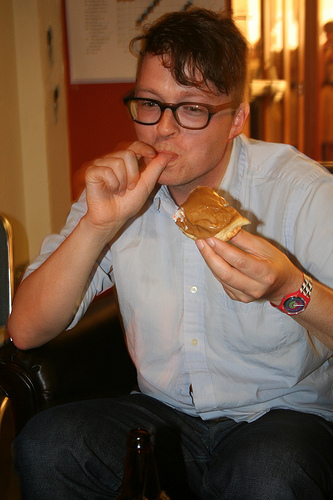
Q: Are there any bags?
A: No, there are no bags.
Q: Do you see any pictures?
A: No, there are no pictures.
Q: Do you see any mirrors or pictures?
A: No, there are no pictures or mirrors.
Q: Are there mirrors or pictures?
A: No, there are no pictures or mirrors.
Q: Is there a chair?
A: Yes, there is a chair.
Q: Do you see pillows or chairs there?
A: Yes, there is a chair.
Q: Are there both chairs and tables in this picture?
A: No, there is a chair but no tables.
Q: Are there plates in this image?
A: No, there are no plates.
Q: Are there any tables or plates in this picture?
A: No, there are no plates or tables.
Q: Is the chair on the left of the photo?
A: Yes, the chair is on the left of the image.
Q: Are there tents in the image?
A: No, there are no tents.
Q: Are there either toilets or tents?
A: No, there are no tents or toilets.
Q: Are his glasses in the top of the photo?
A: Yes, the glasses are in the top of the image.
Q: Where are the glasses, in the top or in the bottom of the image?
A: The glasses are in the top of the image.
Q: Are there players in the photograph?
A: No, there are no players.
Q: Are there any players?
A: No, there are no players.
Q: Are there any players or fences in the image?
A: No, there are no players or fences.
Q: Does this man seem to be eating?
A: Yes, the man is eating.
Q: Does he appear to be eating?
A: Yes, the man is eating.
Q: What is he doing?
A: The man is eating.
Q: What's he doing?
A: The man is eating.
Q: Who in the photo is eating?
A: The man is eating.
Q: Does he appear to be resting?
A: No, the man is eating.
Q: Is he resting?
A: No, the man is eating.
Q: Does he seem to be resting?
A: No, the man is eating.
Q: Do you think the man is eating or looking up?
A: The man is eating.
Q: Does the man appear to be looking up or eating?
A: The man is eating.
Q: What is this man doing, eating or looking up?
A: The man is eating.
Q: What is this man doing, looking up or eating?
A: The man is eating.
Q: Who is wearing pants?
A: The man is wearing pants.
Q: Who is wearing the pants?
A: The man is wearing pants.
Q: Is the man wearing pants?
A: Yes, the man is wearing pants.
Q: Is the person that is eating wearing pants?
A: Yes, the man is wearing pants.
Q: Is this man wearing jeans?
A: No, the man is wearing pants.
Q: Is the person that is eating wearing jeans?
A: No, the man is wearing pants.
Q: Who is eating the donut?
A: The man is eating the donut.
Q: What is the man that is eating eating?
A: The man is eating a doughnut.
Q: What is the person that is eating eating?
A: The man is eating a doughnut.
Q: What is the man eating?
A: The man is eating a doughnut.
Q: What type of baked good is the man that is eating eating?
A: The man is eating a donut.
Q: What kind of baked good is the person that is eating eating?
A: The man is eating a donut.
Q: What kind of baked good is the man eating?
A: The man is eating a donut.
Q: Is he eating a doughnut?
A: Yes, the man is eating a doughnut.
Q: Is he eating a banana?
A: No, the man is eating a doughnut.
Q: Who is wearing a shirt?
A: The man is wearing a shirt.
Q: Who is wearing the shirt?
A: The man is wearing a shirt.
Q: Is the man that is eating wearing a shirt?
A: Yes, the man is wearing a shirt.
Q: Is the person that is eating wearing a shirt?
A: Yes, the man is wearing a shirt.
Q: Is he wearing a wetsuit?
A: No, the man is wearing a shirt.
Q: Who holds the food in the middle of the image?
A: The man holds the doughnut.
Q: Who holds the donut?
A: The man holds the doughnut.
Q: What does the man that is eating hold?
A: The man holds the donut.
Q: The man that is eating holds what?
A: The man holds the donut.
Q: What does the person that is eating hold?
A: The man holds the donut.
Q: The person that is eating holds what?
A: The man holds the donut.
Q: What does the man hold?
A: The man holds the donut.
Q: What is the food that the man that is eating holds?
A: The food is a donut.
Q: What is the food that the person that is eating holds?
A: The food is a donut.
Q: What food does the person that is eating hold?
A: The man holds the donut.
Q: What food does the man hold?
A: The man holds the donut.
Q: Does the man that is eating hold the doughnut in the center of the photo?
A: Yes, the man holds the doughnut.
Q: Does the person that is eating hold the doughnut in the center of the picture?
A: Yes, the man holds the doughnut.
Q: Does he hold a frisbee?
A: No, the man holds the doughnut.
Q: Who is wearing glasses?
A: The man is wearing glasses.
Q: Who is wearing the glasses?
A: The man is wearing glasses.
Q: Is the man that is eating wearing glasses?
A: Yes, the man is wearing glasses.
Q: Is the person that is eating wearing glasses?
A: Yes, the man is wearing glasses.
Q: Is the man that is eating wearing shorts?
A: No, the man is wearing glasses.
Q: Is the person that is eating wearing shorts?
A: No, the man is wearing glasses.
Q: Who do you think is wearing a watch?
A: The man is wearing a watch.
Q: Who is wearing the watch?
A: The man is wearing a watch.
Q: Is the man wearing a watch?
A: Yes, the man is wearing a watch.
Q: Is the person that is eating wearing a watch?
A: Yes, the man is wearing a watch.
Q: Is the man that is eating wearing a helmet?
A: No, the man is wearing a watch.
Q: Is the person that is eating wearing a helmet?
A: No, the man is wearing a watch.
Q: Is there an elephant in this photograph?
A: No, there are no elephants.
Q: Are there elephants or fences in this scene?
A: No, there are no elephants or fences.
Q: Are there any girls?
A: No, there are no girls.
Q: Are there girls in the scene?
A: No, there are no girls.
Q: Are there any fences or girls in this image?
A: No, there are no girls or fences.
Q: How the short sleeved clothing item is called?
A: The clothing item is a shirt.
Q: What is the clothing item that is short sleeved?
A: The clothing item is a shirt.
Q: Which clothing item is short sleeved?
A: The clothing item is a shirt.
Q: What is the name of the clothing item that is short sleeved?
A: The clothing item is a shirt.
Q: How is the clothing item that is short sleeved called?
A: The clothing item is a shirt.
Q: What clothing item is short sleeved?
A: The clothing item is a shirt.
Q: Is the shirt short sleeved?
A: Yes, the shirt is short sleeved.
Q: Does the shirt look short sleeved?
A: Yes, the shirt is short sleeved.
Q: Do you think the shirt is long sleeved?
A: No, the shirt is short sleeved.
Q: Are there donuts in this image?
A: Yes, there is a donut.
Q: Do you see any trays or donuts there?
A: Yes, there is a donut.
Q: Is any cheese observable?
A: No, there is no cheese.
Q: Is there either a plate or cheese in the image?
A: No, there are no cheese or plates.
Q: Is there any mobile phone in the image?
A: No, there are no cell phones.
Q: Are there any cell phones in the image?
A: No, there are no cell phones.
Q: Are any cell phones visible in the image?
A: No, there are no cell phones.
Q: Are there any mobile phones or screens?
A: No, there are no mobile phones or screens.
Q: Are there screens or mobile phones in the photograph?
A: No, there are no mobile phones or screens.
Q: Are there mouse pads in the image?
A: No, there are no mouse pads.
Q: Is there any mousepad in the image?
A: No, there are no mouse pads.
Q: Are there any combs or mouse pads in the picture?
A: No, there are no mouse pads or combs.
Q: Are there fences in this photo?
A: No, there are no fences.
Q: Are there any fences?
A: No, there are no fences.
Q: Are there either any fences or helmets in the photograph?
A: No, there are no fences or helmets.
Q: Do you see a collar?
A: Yes, there is a collar.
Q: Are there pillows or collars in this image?
A: Yes, there is a collar.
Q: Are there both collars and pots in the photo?
A: No, there is a collar but no pots.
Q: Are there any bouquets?
A: No, there are no bouquets.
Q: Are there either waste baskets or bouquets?
A: No, there are no bouquets or waste baskets.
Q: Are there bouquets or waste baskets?
A: No, there are no bouquets or waste baskets.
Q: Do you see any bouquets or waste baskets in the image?
A: No, there are no bouquets or waste baskets.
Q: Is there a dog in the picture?
A: No, there are no dogs.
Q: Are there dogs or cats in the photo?
A: No, there are no dogs or cats.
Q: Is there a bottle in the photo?
A: Yes, there is a bottle.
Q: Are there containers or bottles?
A: Yes, there is a bottle.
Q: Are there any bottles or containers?
A: Yes, there is a bottle.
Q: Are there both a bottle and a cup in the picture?
A: No, there is a bottle but no cups.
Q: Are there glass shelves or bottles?
A: Yes, there is a glass bottle.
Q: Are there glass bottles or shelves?
A: Yes, there is a glass bottle.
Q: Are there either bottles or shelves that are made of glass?
A: Yes, the bottle is made of glass.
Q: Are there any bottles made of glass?
A: Yes, there is a bottle that is made of glass.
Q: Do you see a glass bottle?
A: Yes, there is a bottle that is made of glass.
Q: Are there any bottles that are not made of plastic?
A: Yes, there is a bottle that is made of glass.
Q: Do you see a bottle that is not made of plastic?
A: Yes, there is a bottle that is made of glass.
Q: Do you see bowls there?
A: No, there are no bowls.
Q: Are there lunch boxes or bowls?
A: No, there are no bowls or lunch boxes.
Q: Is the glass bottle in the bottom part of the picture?
A: Yes, the bottle is in the bottom of the image.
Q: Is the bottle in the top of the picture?
A: No, the bottle is in the bottom of the image.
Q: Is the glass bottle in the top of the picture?
A: No, the bottle is in the bottom of the image.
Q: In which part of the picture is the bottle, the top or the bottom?
A: The bottle is in the bottom of the image.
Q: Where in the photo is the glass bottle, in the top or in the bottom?
A: The bottle is in the bottom of the image.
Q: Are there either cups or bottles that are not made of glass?
A: No, there is a bottle but it is made of glass.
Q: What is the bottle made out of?
A: The bottle is made of glass.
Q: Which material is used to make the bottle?
A: The bottle is made of glass.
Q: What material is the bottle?
A: The bottle is made of glass.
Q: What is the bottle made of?
A: The bottle is made of glass.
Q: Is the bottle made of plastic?
A: No, the bottle is made of glass.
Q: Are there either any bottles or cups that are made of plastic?
A: No, there is a bottle but it is made of glass.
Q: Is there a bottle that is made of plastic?
A: No, there is a bottle but it is made of glass.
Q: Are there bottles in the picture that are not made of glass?
A: No, there is a bottle but it is made of glass.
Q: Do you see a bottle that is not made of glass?
A: No, there is a bottle but it is made of glass.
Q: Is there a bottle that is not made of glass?
A: No, there is a bottle but it is made of glass.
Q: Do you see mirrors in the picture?
A: No, there are no mirrors.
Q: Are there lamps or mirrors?
A: No, there are no mirrors or lamps.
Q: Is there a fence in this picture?
A: No, there are no fences.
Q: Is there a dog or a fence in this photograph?
A: No, there are no fences or dogs.